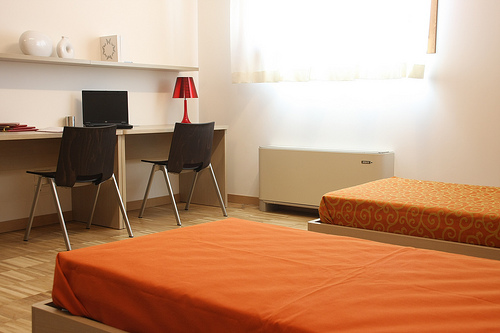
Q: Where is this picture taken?
A: Bedroom.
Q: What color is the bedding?
A: Orange.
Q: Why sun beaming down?
A: Blinds.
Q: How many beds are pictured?
A: Two.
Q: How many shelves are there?
A: One.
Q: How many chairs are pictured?
A: Two.